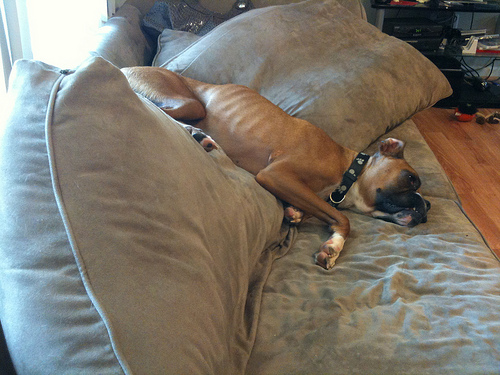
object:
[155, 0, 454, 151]
cushion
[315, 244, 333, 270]
paw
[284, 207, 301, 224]
paw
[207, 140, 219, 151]
paw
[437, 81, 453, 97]
corner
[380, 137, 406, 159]
ear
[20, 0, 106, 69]
window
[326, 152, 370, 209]
collar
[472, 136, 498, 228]
brown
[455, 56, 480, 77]
black wires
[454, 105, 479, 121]
toys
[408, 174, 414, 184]
eye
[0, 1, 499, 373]
couch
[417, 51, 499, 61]
table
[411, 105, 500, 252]
floor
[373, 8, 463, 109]
entertainment system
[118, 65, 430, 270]
boxer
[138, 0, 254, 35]
denim